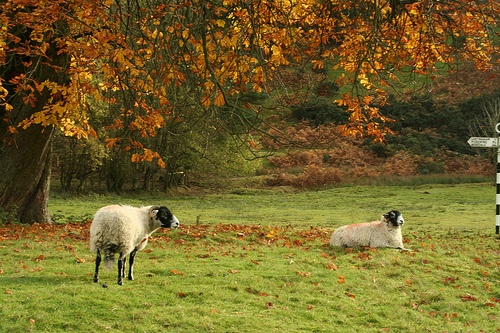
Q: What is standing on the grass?
A: A sheep.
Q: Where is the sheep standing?
A: In the grass.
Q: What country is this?
A: Ireland.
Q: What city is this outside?
A: Dublin.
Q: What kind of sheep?
A: White sheep.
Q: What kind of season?
A: Autumn.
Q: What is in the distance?
A: A sign.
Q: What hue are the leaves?
A: Orange.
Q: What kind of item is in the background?
A: A tree trunk.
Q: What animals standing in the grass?
A: Sheep.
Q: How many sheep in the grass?
A: Two.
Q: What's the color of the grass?
A: Green.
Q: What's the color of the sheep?
A: White.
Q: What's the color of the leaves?
A: Orange.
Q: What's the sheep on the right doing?
A: Lying down.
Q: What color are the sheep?
A: White.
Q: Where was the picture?
A: The farm.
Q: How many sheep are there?
A: Two.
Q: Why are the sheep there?
A: They are at pasture.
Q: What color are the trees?
A: Orange.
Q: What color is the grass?
A: Green.